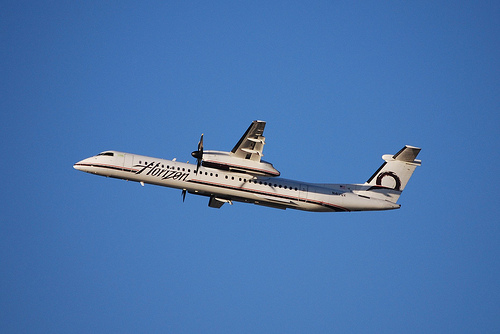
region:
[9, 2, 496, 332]
the sky is clear and blue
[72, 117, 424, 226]
the airplane is white with dark striping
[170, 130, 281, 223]
the engines are turbo props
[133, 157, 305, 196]
windows are on the length of the fuselage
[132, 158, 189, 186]
writing is on the fuselage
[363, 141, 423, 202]
the tail of the plane has a logo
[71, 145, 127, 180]
the cockpit of the plane is white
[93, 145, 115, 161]
windows are on the cockpit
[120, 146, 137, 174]
a door on the fuselage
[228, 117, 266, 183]
the wing of the airplane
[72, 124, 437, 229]
The plane is white.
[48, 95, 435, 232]
The plane is in the air.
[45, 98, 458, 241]
The plane is airborne.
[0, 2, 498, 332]
The sky is blue.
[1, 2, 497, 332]
The sky is clear.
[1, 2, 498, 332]
The sky is cloudless.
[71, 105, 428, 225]
The plane belongs to Horizon.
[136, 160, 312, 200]
The plane has windows.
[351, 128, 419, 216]
A black ring on the tail of plane.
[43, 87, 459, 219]
The plane has a stripe down side.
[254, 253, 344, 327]
The sky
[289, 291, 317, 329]
The sky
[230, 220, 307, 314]
The sky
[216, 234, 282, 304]
The sky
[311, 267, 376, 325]
The sky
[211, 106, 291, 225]
A plane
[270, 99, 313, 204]
A plane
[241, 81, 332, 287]
A plane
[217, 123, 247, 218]
A plane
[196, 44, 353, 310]
A plane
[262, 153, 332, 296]
A plane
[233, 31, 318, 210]
A plane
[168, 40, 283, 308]
A plane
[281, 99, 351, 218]
A plane